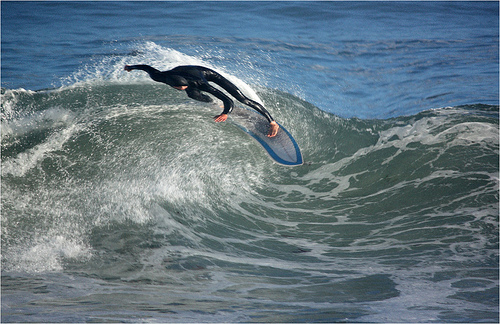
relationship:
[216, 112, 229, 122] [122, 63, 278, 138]
hand of man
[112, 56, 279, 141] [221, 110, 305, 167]
person riding surfboard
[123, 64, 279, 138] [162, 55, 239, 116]
person with wetsuit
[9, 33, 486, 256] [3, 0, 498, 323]
wave on ocean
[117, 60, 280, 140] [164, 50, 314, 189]
surfer in a daring pose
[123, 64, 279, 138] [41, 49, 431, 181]
person on wave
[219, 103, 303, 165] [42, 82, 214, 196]
surfboard on wave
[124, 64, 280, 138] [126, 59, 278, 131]
man wears wetsuit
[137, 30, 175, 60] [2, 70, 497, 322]
spray on wave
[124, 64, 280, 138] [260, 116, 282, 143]
man has foot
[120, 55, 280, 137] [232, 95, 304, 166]
man on surfboard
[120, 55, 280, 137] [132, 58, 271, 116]
man on wet suit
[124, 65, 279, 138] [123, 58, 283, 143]
surfer wears wet suit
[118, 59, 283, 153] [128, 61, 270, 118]
swimmer wears wet suit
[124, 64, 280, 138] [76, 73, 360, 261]
man on waves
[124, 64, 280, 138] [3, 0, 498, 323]
man in ocean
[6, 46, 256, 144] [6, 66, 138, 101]
wave has crest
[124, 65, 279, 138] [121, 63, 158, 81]
surfer has arm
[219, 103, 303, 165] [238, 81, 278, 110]
surfboard make wake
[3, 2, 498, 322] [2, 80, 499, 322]
sea has foam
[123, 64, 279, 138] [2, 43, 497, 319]
person in water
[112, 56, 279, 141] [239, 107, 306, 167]
person on surfboard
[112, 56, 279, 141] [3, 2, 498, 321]
person in water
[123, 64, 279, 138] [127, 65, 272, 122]
person wears wetsuit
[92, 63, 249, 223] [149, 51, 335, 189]
waves behind person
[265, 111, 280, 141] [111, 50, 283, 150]
foot on surfer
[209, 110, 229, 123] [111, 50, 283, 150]
foot on surfer